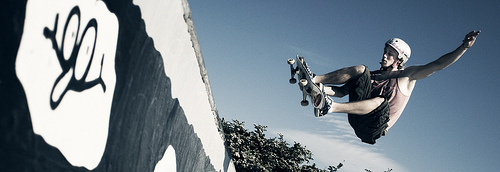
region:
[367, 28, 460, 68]
the head of aman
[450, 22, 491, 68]
the hand of a man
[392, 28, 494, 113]
the arm of a man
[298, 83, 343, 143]
the foot of a man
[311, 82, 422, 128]
the leg of a man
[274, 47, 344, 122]
the wheels on a skateboard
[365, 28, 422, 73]
a man wearing a helmet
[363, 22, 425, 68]
the face of a man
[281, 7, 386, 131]
a skateboard in the air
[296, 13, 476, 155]
a man in the air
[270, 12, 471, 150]
the man is skateboarding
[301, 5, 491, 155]
the arm is out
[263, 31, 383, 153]
the man is holding the side of the skateboard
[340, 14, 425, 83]
ma is wearing a helmet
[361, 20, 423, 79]
the helmet is white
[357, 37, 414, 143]
man is wearing a tank top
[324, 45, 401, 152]
the man is wearing shorts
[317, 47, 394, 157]
the shorts are black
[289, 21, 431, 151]
the man is squatting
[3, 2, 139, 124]
a face on the ramp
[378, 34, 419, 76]
boy has white helmet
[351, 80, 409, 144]
boy has orange shirt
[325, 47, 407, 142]
boy has dark shorts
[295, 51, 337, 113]
tan wheel on skateboard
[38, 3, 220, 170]
black and white graffiti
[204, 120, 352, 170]
green trees in distance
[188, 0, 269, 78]
sky is blue and clear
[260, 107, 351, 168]
few thin clouds in sky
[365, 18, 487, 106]
left arm is extended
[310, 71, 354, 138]
boy has white shoes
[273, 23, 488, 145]
man riding a skateboard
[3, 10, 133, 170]
black and white painted face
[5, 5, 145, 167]
black and white paint on the wall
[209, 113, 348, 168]
tree with green leaves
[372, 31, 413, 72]
man wearing a white helmet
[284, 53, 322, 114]
white wheels on a skateboard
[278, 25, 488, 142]
man wearing red tank top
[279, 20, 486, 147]
man wearing black shorts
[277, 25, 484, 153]
man with one arm in air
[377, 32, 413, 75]
white helmet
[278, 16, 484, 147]
Skate boarder in the air.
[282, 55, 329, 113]
Skate board with four wheels.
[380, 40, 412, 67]
Skate boarder wearing a helmet.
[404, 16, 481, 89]
Skate boarders arm outstretched.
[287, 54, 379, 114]
One arm holding on to the skate board.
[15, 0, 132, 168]
Advertisement on the wall.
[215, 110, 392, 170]
Trees in the background.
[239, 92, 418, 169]
White clouds in the sky.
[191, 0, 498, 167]
Blue sky in the background.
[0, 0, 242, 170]
White and black wall that skater is using.